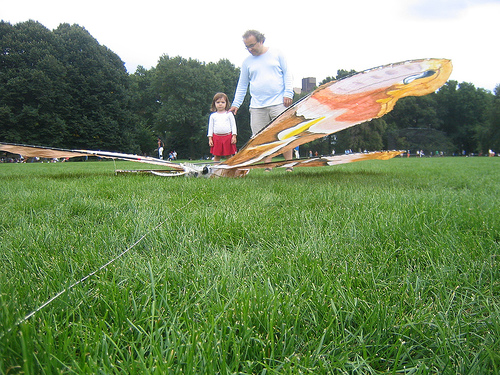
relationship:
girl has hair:
[195, 85, 237, 169] [208, 81, 232, 119]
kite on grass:
[9, 49, 455, 177] [9, 162, 496, 369]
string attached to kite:
[7, 169, 210, 374] [2, 54, 452, 195]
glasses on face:
[241, 42, 262, 51] [239, 35, 264, 55]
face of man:
[239, 35, 264, 55] [227, 24, 296, 126]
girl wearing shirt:
[207, 90, 234, 178] [189, 101, 239, 125]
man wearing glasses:
[226, 27, 298, 177] [242, 41, 268, 52]